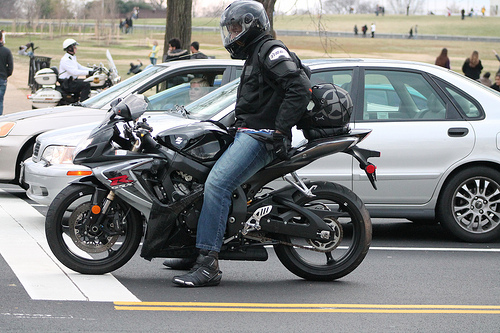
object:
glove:
[241, 130, 283, 146]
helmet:
[293, 83, 355, 141]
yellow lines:
[109, 305, 499, 313]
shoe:
[171, 255, 222, 287]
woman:
[184, 76, 215, 102]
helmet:
[58, 38, 79, 52]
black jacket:
[233, 35, 312, 134]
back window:
[362, 66, 483, 121]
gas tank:
[155, 121, 233, 163]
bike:
[44, 82, 381, 279]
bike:
[29, 48, 124, 109]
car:
[17, 58, 500, 243]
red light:
[364, 163, 374, 173]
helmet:
[218, 0, 273, 60]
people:
[367, 22, 377, 39]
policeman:
[57, 38, 102, 105]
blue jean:
[194, 128, 276, 254]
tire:
[272, 180, 373, 282]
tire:
[42, 175, 146, 274]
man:
[161, 0, 314, 287]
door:
[350, 67, 476, 206]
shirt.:
[56, 52, 89, 81]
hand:
[243, 125, 284, 142]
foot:
[170, 252, 222, 288]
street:
[0, 176, 499, 333]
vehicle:
[0, 58, 305, 191]